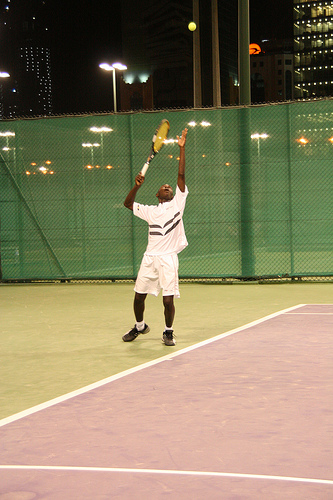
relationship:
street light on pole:
[94, 53, 140, 71] [99, 74, 131, 122]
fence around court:
[0, 94, 331, 286] [2, 277, 332, 494]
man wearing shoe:
[120, 122, 188, 346] [121, 322, 150, 343]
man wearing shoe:
[120, 122, 188, 346] [162, 328, 174, 347]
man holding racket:
[120, 122, 188, 346] [136, 114, 179, 176]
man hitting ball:
[120, 122, 188, 346] [187, 19, 197, 33]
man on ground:
[120, 122, 188, 346] [1, 282, 332, 498]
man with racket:
[120, 118, 188, 345] [139, 118, 169, 184]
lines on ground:
[1, 302, 331, 483] [1, 282, 332, 498]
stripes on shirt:
[148, 211, 179, 235] [131, 184, 189, 252]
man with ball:
[120, 122, 188, 346] [187, 21, 197, 32]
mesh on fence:
[0, 95, 332, 281] [0, 94, 331, 286]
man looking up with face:
[120, 122, 188, 346] [158, 182, 174, 198]